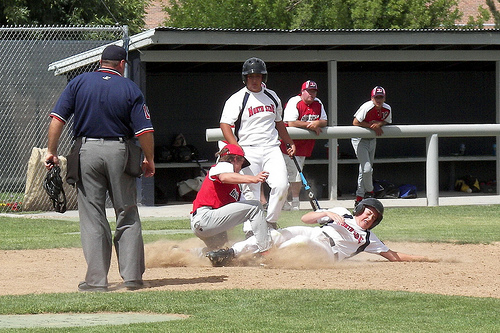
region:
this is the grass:
[245, 291, 334, 331]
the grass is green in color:
[241, 288, 306, 330]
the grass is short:
[239, 292, 344, 332]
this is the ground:
[382, 265, 476, 284]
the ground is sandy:
[402, 270, 482, 284]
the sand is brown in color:
[397, 267, 485, 282]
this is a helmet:
[354, 198, 386, 218]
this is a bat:
[281, 145, 328, 205]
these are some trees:
[273, 0, 398, 25]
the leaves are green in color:
[316, 0, 408, 27]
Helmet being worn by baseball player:
[238, 53, 270, 92]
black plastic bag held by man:
[37, 148, 70, 215]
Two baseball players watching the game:
[273, 72, 399, 210]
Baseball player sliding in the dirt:
[203, 188, 435, 270]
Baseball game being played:
[37, 43, 463, 326]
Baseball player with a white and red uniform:
[186, 139, 289, 273]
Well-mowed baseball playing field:
[7, 195, 488, 325]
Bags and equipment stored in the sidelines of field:
[156, 117, 493, 203]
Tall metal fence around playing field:
[3, 18, 138, 218]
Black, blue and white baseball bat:
[280, 139, 325, 217]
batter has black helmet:
[230, 48, 272, 83]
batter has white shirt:
[220, 78, 316, 153]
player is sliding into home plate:
[231, 196, 407, 282]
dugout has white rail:
[265, 112, 470, 188]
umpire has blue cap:
[96, 36, 127, 54]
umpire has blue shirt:
[40, 71, 138, 139]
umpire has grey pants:
[60, 142, 158, 282]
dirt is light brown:
[347, 243, 495, 278]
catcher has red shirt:
[192, 160, 278, 231]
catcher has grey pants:
[186, 204, 285, 254]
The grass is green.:
[240, 299, 355, 331]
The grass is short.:
[233, 302, 367, 331]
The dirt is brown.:
[438, 270, 491, 287]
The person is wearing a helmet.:
[226, 47, 279, 94]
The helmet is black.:
[233, 46, 269, 89]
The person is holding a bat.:
[273, 130, 335, 229]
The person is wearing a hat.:
[203, 134, 258, 171]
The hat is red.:
[203, 137, 262, 168]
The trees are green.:
[163, 1, 458, 31]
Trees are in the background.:
[166, 0, 453, 31]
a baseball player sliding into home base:
[281, 189, 394, 266]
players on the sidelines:
[293, 74, 406, 138]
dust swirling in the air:
[276, 241, 327, 268]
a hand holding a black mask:
[40, 151, 66, 168]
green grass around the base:
[227, 296, 315, 331]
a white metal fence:
[417, 113, 446, 203]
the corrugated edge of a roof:
[184, 25, 497, 35]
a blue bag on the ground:
[397, 182, 426, 199]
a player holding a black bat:
[235, 60, 286, 157]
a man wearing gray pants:
[69, 36, 164, 296]